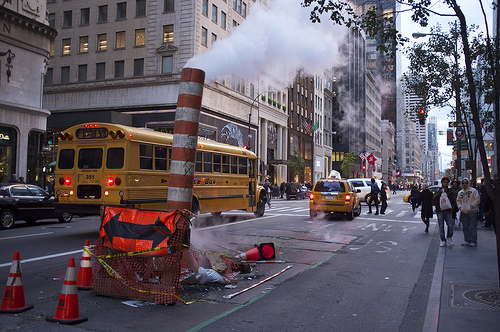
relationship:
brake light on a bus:
[104, 176, 117, 188] [49, 120, 272, 227]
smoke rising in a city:
[184, 0, 364, 89] [7, 1, 481, 315]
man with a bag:
[430, 175, 462, 248] [439, 188, 454, 210]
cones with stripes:
[0, 224, 102, 324] [0, 259, 83, 299]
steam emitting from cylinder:
[177, 4, 357, 84] [165, 62, 206, 207]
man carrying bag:
[429, 171, 461, 248] [439, 187, 458, 225]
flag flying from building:
[302, 117, 313, 134] [44, 0, 396, 197]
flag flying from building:
[359, 152, 367, 160] [397, 74, 438, 185]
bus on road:
[55, 116, 270, 216] [3, 166, 428, 326]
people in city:
[16, 182, 498, 275] [7, 1, 481, 315]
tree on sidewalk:
[304, 1, 499, 197] [433, 217, 482, 329]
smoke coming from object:
[181, 0, 376, 84] [167, 62, 205, 255]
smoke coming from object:
[190, 210, 232, 255] [167, 62, 205, 255]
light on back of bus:
[102, 173, 112, 188] [55, 116, 270, 216]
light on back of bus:
[61, 173, 71, 186] [55, 116, 270, 216]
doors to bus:
[246, 157, 256, 209] [55, 116, 270, 216]